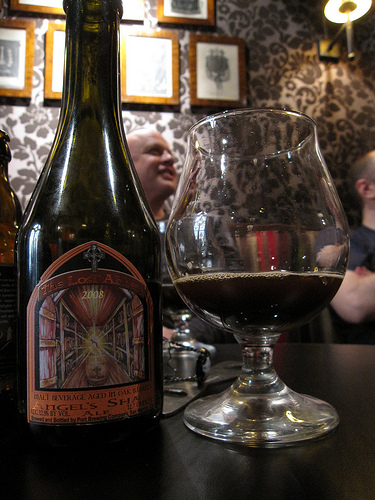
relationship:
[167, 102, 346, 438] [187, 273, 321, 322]
glass holding wine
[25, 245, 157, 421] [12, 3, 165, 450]
label stuck on bottle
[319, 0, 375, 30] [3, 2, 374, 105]
light mounted on wall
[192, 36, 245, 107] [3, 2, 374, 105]
picture hanging on wall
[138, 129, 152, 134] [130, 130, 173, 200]
light shining on head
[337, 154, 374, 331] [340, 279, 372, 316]
man crossing arm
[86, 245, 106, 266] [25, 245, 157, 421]
cross on label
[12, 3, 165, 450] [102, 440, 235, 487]
bottle on top of table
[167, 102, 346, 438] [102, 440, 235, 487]
glass on top of table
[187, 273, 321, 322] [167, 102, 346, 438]
wine inside of glass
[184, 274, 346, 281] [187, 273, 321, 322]
bubble on top of wine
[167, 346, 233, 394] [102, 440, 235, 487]
bottle opener on top of table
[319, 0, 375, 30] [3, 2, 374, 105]
light hanging on wall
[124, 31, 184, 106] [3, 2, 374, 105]
picture hanging on wall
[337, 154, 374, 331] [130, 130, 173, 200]
man has head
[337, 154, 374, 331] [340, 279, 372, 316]
man folding arm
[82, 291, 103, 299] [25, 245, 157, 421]
date printed on label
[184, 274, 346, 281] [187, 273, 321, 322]
bubble floating in wine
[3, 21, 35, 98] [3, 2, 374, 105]
picture hanging on wall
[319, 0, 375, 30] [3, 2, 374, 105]
light attached to wall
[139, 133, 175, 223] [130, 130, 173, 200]
man has head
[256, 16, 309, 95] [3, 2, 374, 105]
wallpaper hung on wall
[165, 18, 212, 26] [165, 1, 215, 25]
frame around picture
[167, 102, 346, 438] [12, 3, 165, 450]
glass next to bottle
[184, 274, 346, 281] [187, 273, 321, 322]
bubble floating on wine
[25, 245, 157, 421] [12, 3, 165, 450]
label attached to bottle